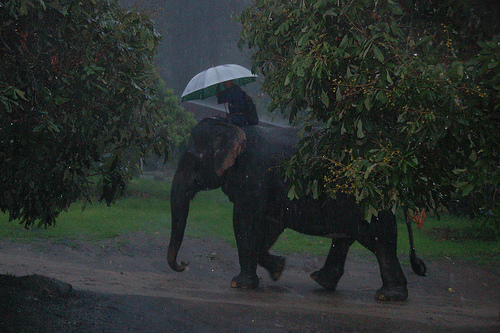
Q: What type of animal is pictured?
A: An elephant.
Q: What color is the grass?
A: Green.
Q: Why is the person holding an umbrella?
A: Because it is raining.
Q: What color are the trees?
A: Green.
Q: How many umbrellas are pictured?
A: One.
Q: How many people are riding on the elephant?
A: One.